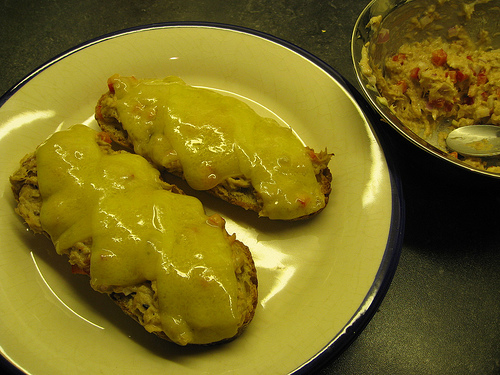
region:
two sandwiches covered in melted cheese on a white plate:
[15, 65, 354, 350]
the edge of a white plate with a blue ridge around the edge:
[335, 140, 416, 327]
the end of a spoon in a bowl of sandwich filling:
[450, 122, 499, 159]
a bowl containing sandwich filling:
[349, 1, 499, 183]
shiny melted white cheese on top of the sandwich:
[159, 232, 222, 328]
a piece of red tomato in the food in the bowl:
[426, 46, 450, 71]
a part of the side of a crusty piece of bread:
[213, 185, 268, 220]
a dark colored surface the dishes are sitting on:
[409, 243, 491, 372]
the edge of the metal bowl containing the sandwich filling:
[350, 15, 372, 96]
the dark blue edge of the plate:
[375, 226, 401, 275]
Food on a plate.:
[16, 68, 333, 358]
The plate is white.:
[0, 19, 408, 366]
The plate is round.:
[5, 19, 395, 374]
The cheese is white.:
[40, 127, 233, 329]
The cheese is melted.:
[31, 116, 237, 349]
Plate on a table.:
[2, 17, 424, 367]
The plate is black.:
[4, 5, 498, 372]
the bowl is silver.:
[337, 2, 497, 187]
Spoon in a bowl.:
[434, 112, 499, 158]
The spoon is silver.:
[442, 115, 499, 156]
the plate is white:
[106, 122, 297, 372]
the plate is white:
[184, 105, 459, 367]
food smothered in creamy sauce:
[10, 30, 402, 365]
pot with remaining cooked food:
[345, 0, 495, 185]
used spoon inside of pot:
[432, 112, 492, 182]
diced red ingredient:
[382, 30, 494, 110]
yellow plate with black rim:
[0, 25, 385, 365]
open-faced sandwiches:
[15, 66, 355, 348]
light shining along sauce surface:
[47, 125, 242, 321]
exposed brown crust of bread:
[235, 230, 261, 326]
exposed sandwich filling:
[117, 285, 157, 335]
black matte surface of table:
[361, 182, 492, 365]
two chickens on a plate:
[21, 18, 342, 359]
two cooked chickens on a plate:
[4, 15, 447, 373]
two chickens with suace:
[7, 16, 397, 348]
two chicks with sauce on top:
[7, 18, 414, 373]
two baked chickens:
[17, 16, 389, 335]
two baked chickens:
[32, 7, 447, 341]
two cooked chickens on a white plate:
[7, 18, 471, 360]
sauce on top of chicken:
[5, 14, 439, 367]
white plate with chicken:
[10, 10, 457, 339]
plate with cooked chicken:
[7, 9, 469, 371]